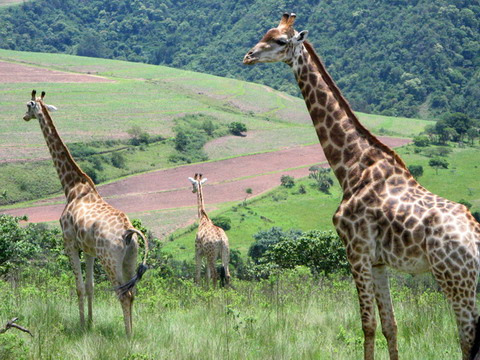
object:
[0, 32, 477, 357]
field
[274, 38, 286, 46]
eye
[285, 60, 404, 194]
neck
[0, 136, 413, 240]
path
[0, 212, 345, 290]
shrubbery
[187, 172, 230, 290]
giraffe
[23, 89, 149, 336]
giraffe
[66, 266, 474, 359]
grass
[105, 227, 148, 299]
tail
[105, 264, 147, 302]
hair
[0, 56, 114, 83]
area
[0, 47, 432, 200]
hill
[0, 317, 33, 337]
branch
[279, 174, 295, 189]
bush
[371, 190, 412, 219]
spot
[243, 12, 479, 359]
giraffe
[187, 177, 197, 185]
horn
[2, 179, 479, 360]
cliff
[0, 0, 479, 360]
landscape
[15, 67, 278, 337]
companions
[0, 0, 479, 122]
forest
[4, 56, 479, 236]
plain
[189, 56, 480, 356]
savannah